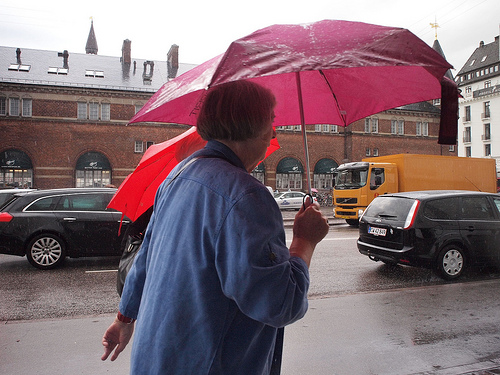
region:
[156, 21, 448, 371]
a person with a red umbrella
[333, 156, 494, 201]
A yellow truck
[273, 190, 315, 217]
a white car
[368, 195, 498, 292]
a black car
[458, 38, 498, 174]
a white building with windows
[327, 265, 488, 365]
a grey rain soaked roadway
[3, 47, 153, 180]
a red brick building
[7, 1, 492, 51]
a grey rainy sky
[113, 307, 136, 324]
a red watch band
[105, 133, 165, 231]
a bright red umbrella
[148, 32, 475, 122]
Maroon umbrella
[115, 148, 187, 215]
Red umbrella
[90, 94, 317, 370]
Woman walking with an umbrella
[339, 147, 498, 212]
Orange truck driving on the street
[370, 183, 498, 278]
Black car driving on the wet street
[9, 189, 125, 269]
Black vehicle driving on the street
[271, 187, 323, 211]
White car parked in a parking lot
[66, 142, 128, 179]
Green awning on a brick building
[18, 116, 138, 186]
Brick building next to the road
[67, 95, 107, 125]
Windows on a brick building next to the road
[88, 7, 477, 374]
the woman is holding a red umbrella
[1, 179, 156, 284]
the car is black with silver rims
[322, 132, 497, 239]
the truck is yellow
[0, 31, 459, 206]
the building is brown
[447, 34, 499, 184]
the white building has windows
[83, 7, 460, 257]
the umbrellas are different shades of red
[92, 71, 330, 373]
the woman is wearing a blue shirt and brown watch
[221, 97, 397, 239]
a white car sits in front of the brown building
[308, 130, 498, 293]
a black car on the road is in front of the yellow truck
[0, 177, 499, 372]
the road is dark and wet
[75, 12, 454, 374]
a woman carrying a pink umbrella in the rain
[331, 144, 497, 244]
a yellow truck in the background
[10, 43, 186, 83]
chimneys on the top of a building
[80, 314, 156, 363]
the free left hand on the woman holding the umbrella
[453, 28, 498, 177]
a tall white building in the distance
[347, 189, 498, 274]
a black station wagon type car that is parked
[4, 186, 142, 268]
a parked black station wagon type car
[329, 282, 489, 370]
a wet black paved parking lot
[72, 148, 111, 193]
an arched window on an old brick building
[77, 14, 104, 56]
a pointed church steeple in the distance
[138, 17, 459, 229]
a purple umbrella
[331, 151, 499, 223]
an orange truck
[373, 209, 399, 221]
a black windshield wiper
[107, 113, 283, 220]
a red umbrella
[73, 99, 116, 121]
three windows in a row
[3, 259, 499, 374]
rain hitting the road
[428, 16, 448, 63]
a cross on top of a building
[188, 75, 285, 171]
a woman with short hair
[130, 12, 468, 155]
a wet umbrella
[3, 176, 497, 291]
two black cars on the road